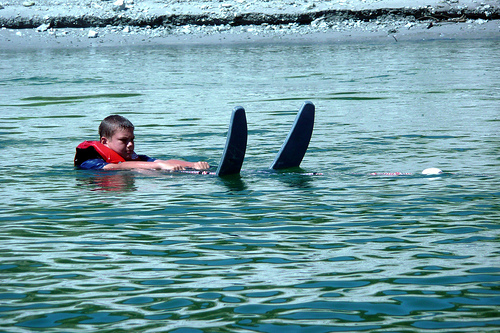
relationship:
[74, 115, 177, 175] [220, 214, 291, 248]
person floating on water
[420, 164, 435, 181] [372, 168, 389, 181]
bobber attached to ski rope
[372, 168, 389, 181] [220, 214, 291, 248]
ski rope on top of water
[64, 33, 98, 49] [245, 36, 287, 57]
sand on top of shore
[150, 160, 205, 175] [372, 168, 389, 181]
hands holding onto ski rope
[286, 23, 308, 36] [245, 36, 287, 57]
rock by shore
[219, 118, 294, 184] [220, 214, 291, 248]
skis sticking out of water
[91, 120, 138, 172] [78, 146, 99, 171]
boy wearing a vest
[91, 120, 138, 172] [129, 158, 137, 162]
boy wearing a shirt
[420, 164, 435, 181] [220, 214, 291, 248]
bobber on top of water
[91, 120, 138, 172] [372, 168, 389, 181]
boy holding onto ski rope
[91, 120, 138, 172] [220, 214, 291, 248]
boy in water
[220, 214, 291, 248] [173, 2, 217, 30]
water connects to beach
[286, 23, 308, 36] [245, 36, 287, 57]
rock alongside shore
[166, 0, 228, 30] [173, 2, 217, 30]
ledge behind beach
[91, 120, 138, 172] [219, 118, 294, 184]
boy has skis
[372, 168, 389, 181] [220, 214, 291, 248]
ski rope in water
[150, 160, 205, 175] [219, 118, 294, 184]
hands hold skis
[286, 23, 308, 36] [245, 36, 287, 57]
rock in shore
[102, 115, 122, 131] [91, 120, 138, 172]
hair of boy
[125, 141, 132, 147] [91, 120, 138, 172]
nose of boy